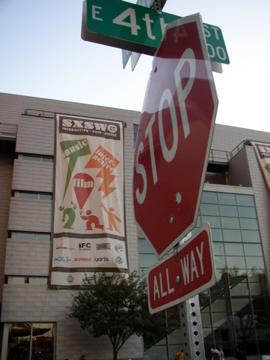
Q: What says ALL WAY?
A: The sign.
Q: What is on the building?
A: The banner.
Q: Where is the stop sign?
A: On the pole.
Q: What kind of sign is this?
A: Stop sign.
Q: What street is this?
A: 4th st.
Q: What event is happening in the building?
A: SXSW.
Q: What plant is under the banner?
A: Tree.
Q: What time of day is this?
A: Afternoon.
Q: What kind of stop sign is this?
A: All way.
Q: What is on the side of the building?
A: A sign.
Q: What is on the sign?
A: SXSW.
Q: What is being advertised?
A: SXSW.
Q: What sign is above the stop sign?
A: E 4th St.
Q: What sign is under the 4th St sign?
A: The stop sign.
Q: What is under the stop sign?
A: An All Way sign.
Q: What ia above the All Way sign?
A: A stop sign.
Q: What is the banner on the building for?
A: SXSW.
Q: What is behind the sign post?
A: A building.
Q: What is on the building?
A: An ad.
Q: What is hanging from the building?
A: A giant ad on the building.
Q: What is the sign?
A: A red STOP sign.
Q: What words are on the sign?
A: Stop.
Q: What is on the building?
A: Windows.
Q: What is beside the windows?
A: Tree.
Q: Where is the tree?
A: In front of the wall.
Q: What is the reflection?
A: Staircase.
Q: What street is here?
A: East 4th St.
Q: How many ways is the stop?
A: All ways.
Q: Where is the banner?
A: On the building.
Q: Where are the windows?
A: On the building.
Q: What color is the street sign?
A: Green.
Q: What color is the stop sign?
A: Red.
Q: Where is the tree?
A: Under the banner.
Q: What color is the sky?
A: Blue.